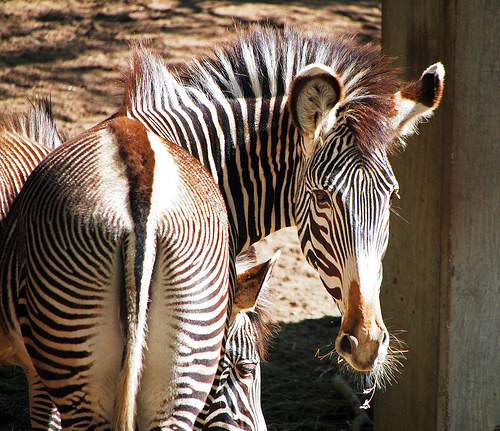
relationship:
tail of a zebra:
[113, 230, 161, 430] [3, 21, 448, 427]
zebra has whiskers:
[3, 21, 448, 427] [382, 357, 395, 383]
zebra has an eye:
[3, 21, 448, 427] [306, 178, 337, 212]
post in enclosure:
[435, 6, 453, 429] [393, 183, 470, 316]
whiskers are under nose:
[316, 332, 415, 387] [330, 325, 394, 375]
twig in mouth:
[335, 366, 384, 397] [333, 357, 386, 411]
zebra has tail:
[1, 92, 283, 431] [116, 212, 156, 427]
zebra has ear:
[1, 92, 283, 431] [218, 251, 278, 331]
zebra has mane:
[121, 38, 450, 428] [169, 33, 386, 100]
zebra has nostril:
[3, 21, 448, 427] [332, 335, 356, 356]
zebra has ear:
[3, 21, 448, 427] [387, 54, 450, 146]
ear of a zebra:
[288, 57, 342, 153] [3, 21, 448, 427]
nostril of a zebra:
[372, 321, 399, 355] [3, 21, 448, 427]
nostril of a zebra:
[333, 335, 354, 364] [3, 21, 448, 427]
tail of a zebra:
[113, 223, 169, 430] [3, 21, 448, 427]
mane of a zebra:
[119, 28, 420, 173] [3, 21, 448, 427]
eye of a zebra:
[306, 181, 335, 213] [3, 21, 448, 427]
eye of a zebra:
[379, 190, 404, 213] [3, 21, 448, 427]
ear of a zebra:
[232, 244, 289, 312] [1, 92, 283, 431]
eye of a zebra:
[232, 355, 270, 389] [1, 92, 283, 431]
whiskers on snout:
[322, 332, 412, 406] [324, 279, 391, 371]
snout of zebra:
[324, 279, 391, 371] [3, 21, 448, 427]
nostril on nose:
[337, 335, 353, 357] [328, 281, 393, 381]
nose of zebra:
[328, 281, 393, 381] [3, 21, 448, 427]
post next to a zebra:
[368, 6, 498, 429] [3, 21, 448, 427]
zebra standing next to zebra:
[3, 21, 448, 427] [1, 92, 283, 431]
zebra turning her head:
[3, 21, 448, 427] [288, 50, 453, 397]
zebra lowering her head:
[1, 92, 257, 430] [206, 272, 276, 430]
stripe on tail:
[117, 115, 166, 316] [112, 119, 181, 429]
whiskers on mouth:
[313, 334, 414, 399] [328, 321, 397, 375]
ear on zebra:
[228, 244, 289, 322] [1, 92, 257, 430]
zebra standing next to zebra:
[3, 21, 448, 427] [1, 92, 257, 430]